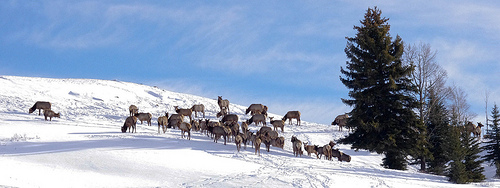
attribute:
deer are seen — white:
[25, 85, 486, 170]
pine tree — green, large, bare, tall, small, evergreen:
[332, 3, 430, 173]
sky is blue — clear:
[2, 3, 498, 132]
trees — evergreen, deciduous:
[339, 6, 499, 186]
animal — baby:
[29, 100, 51, 120]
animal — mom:
[43, 109, 61, 120]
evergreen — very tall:
[340, 5, 426, 155]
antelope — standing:
[216, 95, 230, 115]